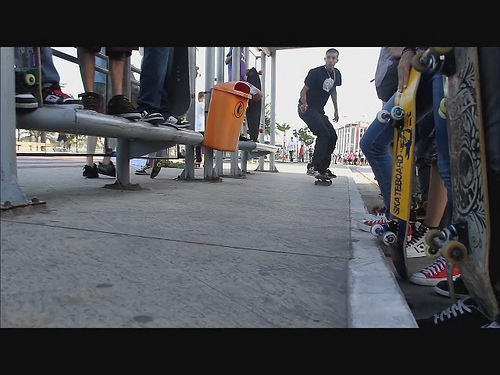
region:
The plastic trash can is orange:
[201, 77, 249, 153]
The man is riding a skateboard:
[295, 46, 340, 181]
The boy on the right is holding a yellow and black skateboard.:
[385, 68, 420, 279]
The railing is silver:
[25, 100, 285, 170]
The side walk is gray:
[0, 155, 347, 317]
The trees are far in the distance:
[265, 115, 315, 150]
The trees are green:
[265, 115, 315, 150]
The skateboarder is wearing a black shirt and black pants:
[296, 65, 345, 172]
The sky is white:
[277, 50, 374, 137]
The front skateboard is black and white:
[428, 47, 496, 313]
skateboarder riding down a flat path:
[35, 30, 476, 310]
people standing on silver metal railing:
[10, 65, 295, 185]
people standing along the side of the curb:
[345, 65, 485, 311]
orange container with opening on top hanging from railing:
[177, 67, 272, 157]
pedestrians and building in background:
[280, 112, 366, 167]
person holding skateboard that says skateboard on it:
[367, 60, 422, 270]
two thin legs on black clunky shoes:
[66, 41, 137, 122]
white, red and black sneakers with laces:
[390, 205, 490, 321]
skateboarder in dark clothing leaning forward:
[290, 46, 340, 191]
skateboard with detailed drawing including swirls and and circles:
[435, 47, 493, 313]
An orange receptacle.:
[203, 76, 256, 156]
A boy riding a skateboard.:
[297, 49, 348, 190]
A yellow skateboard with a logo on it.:
[376, 67, 418, 252]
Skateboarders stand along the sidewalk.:
[358, 49, 493, 319]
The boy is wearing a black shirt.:
[300, 50, 345, 115]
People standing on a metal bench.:
[5, 46, 283, 184]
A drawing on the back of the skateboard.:
[426, 51, 491, 288]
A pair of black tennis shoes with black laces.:
[77, 85, 143, 125]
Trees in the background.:
[260, 96, 315, 168]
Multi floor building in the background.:
[334, 121, 376, 171]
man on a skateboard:
[291, 45, 350, 192]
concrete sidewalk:
[6, 145, 353, 327]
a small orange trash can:
[207, 77, 249, 154]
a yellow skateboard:
[383, 57, 413, 257]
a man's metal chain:
[323, 63, 340, 90]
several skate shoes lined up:
[354, 202, 490, 330]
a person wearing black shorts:
[72, 45, 139, 121]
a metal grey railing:
[5, 30, 283, 213]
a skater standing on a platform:
[6, 40, 82, 112]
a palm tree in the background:
[275, 119, 292, 161]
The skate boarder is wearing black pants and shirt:
[296, 46, 346, 191]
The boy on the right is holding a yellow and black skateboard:
[379, 70, 421, 284]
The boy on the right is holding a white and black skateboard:
[432, 54, 497, 319]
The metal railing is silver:
[9, 106, 282, 191]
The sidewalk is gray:
[9, 163, 353, 325]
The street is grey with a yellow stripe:
[355, 159, 390, 224]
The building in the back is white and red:
[333, 122, 379, 164]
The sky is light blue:
[277, 54, 382, 166]